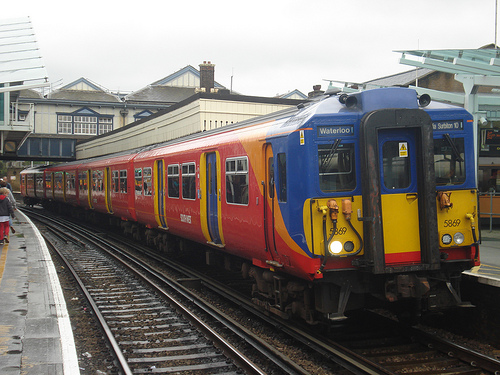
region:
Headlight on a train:
[328, 237, 343, 252]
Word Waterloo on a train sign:
[312, 124, 354, 136]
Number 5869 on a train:
[444, 215, 464, 229]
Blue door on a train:
[204, 150, 221, 245]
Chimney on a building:
[196, 60, 217, 91]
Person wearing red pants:
[0, 218, 14, 243]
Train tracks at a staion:
[64, 248, 271, 372]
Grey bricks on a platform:
[6, 268, 53, 353]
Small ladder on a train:
[267, 258, 286, 310]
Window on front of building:
[53, 111, 113, 134]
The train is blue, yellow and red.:
[218, 90, 493, 284]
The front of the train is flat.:
[282, 80, 482, 311]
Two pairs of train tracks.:
[61, 252, 491, 373]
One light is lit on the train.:
[302, 185, 371, 286]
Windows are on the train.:
[14, 140, 307, 225]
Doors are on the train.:
[3, 136, 313, 276]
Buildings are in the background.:
[2, 34, 281, 151]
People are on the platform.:
[2, 167, 45, 261]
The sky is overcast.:
[53, 16, 177, 56]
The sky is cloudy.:
[49, 10, 176, 58]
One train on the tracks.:
[11, 103, 486, 322]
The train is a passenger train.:
[9, 125, 484, 314]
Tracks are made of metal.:
[24, 198, 495, 374]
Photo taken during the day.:
[8, 4, 494, 366]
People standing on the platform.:
[0, 163, 32, 265]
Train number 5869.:
[439, 213, 469, 232]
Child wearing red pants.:
[0, 181, 12, 246]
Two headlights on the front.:
[328, 226, 472, 255]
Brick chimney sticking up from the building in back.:
[193, 53, 225, 97]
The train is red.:
[18, 137, 474, 297]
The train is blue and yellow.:
[261, 99, 498, 318]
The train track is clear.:
[34, 212, 239, 374]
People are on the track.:
[41, 157, 438, 230]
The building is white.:
[40, 84, 120, 148]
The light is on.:
[322, 233, 354, 265]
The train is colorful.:
[2, 32, 480, 374]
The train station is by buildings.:
[18, 97, 495, 343]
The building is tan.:
[77, 87, 309, 165]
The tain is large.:
[13, 142, 477, 292]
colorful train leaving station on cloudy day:
[36, 30, 467, 337]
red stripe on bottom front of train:
[311, 250, 481, 278]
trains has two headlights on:
[321, 228, 472, 253]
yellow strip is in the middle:
[293, 195, 487, 253]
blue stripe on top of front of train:
[283, 85, 478, 199]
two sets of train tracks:
[76, 305, 470, 349]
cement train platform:
[6, 176, 93, 361]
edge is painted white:
[43, 308, 98, 367]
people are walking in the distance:
[2, 172, 30, 263]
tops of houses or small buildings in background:
[2, 53, 247, 148]